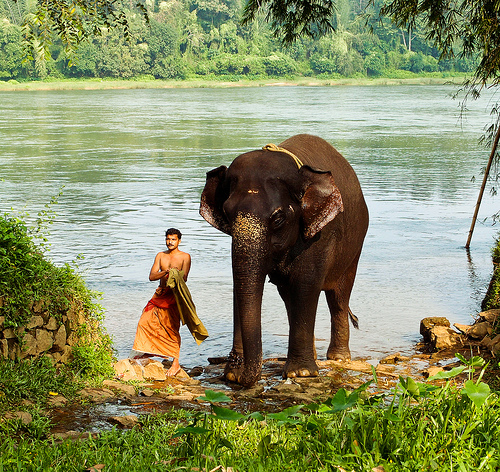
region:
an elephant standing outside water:
[195, 126, 405, 428]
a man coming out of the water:
[129, 206, 212, 377]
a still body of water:
[8, 50, 482, 384]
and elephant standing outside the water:
[191, 113, 410, 420]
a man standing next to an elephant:
[111, 106, 414, 393]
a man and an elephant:
[113, 126, 408, 406]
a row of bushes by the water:
[5, 43, 497, 93]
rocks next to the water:
[377, 302, 499, 389]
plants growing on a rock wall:
[1, 203, 126, 385]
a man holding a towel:
[136, 214, 208, 387]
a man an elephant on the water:
[2, 74, 499, 416]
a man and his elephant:
[132, 125, 371, 392]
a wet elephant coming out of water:
[193, 131, 376, 398]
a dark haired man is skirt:
[126, 220, 211, 392]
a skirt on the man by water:
[130, 221, 192, 365]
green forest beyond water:
[20, 19, 442, 112]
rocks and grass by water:
[0, 295, 117, 415]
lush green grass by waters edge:
[183, 391, 465, 470]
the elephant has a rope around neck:
[240, 135, 331, 201]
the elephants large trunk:
[220, 202, 285, 392]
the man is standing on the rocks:
[135, 224, 202, 362]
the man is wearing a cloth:
[133, 286, 185, 357]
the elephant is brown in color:
[198, 136, 374, 383]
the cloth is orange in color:
[135, 278, 188, 354]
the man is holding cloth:
[163, 267, 205, 341]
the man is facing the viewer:
[148, 223, 195, 361]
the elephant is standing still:
[198, 135, 371, 385]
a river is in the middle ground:
[1, 85, 491, 350]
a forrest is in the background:
[3, 0, 486, 79]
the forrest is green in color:
[2, 2, 499, 75]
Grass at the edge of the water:
[180, 393, 375, 468]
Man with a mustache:
[159, 226, 187, 258]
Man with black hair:
[159, 224, 179, 254]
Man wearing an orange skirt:
[136, 286, 188, 355]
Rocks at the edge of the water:
[415, 315, 479, 361]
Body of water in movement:
[53, 98, 201, 186]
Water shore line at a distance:
[98, 73, 326, 111]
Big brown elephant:
[193, 127, 371, 385]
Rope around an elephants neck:
[246, 135, 321, 188]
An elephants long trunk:
[220, 186, 277, 397]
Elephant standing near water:
[193, 127, 375, 390]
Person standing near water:
[130, 226, 211, 376]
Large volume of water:
[1, 84, 498, 374]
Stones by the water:
[412, 312, 496, 357]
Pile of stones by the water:
[0, 271, 105, 371]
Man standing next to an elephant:
[134, 130, 376, 387]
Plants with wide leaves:
[157, 352, 499, 449]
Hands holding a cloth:
[148, 264, 213, 348]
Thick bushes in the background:
[1, 1, 498, 85]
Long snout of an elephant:
[226, 221, 276, 391]